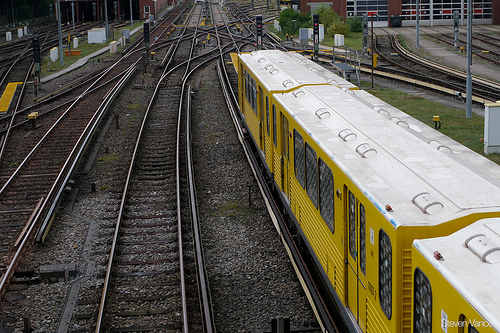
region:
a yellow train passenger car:
[238, 45, 358, 184]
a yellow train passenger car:
[259, 84, 498, 331]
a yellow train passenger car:
[413, 213, 498, 331]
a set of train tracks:
[0, 0, 181, 315]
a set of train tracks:
[85, 0, 207, 332]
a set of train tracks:
[368, 20, 498, 105]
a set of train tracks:
[188, 40, 215, 77]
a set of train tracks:
[15, 73, 85, 127]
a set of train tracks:
[0, 25, 54, 161]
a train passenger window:
[317, 160, 333, 227]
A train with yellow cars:
[225, 38, 465, 329]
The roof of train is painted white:
[322, 79, 444, 213]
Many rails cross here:
[107, 13, 272, 56]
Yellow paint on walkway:
[0, 68, 27, 120]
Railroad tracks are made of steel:
[114, 108, 215, 302]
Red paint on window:
[365, 11, 380, 22]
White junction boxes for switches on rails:
[104, 33, 127, 58]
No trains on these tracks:
[1, 4, 208, 331]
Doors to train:
[329, 185, 376, 331]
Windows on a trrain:
[289, 130, 339, 235]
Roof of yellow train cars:
[233, 38, 497, 300]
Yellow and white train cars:
[225, 52, 497, 332]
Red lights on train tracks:
[246, 12, 333, 48]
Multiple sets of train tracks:
[6, 29, 321, 328]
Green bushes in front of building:
[269, 1, 379, 40]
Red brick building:
[271, 0, 352, 31]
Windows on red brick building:
[339, 2, 496, 37]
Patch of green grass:
[338, 65, 498, 157]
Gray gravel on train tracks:
[106, 116, 288, 331]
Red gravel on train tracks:
[14, 9, 174, 226]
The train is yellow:
[239, 49, 496, 306]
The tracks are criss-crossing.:
[171, 15, 251, 47]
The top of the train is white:
[247, 49, 337, 84]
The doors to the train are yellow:
[342, 189, 369, 321]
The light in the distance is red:
[256, 11, 265, 41]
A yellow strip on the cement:
[3, 78, 22, 110]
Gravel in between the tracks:
[198, 143, 242, 278]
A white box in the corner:
[86, 29, 108, 41]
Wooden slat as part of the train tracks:
[116, 293, 179, 302]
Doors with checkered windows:
[433, 1, 463, 24]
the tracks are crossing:
[170, 10, 242, 51]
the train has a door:
[331, 184, 373, 314]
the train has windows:
[280, 135, 338, 225]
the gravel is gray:
[210, 192, 250, 290]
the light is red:
[246, 12, 265, 39]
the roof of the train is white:
[336, 103, 408, 161]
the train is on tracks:
[215, 44, 490, 328]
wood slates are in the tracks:
[124, 242, 167, 324]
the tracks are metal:
[65, 123, 92, 162]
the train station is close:
[349, 5, 499, 32]